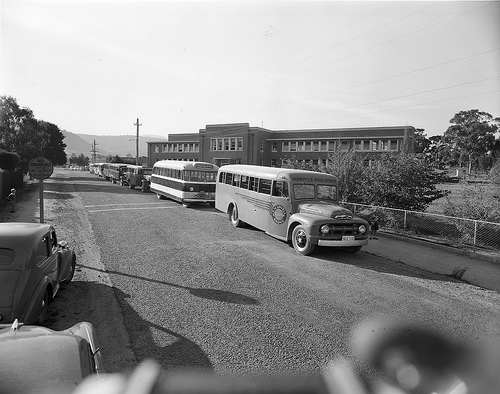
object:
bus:
[215, 162, 371, 256]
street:
[69, 168, 500, 393]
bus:
[150, 159, 218, 206]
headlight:
[321, 225, 330, 235]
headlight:
[358, 225, 367, 234]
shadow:
[43, 191, 75, 197]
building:
[146, 122, 417, 180]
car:
[0, 317, 104, 393]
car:
[0, 221, 77, 323]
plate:
[342, 235, 355, 243]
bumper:
[319, 239, 369, 247]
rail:
[151, 172, 187, 180]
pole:
[136, 117, 140, 164]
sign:
[28, 157, 55, 181]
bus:
[102, 164, 127, 186]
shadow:
[76, 262, 259, 304]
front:
[289, 172, 369, 256]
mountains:
[59, 129, 113, 158]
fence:
[337, 201, 499, 253]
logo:
[235, 192, 288, 224]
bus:
[92, 164, 103, 174]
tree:
[20, 119, 66, 180]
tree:
[0, 149, 22, 169]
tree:
[0, 93, 35, 158]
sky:
[0, 0, 498, 139]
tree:
[441, 108, 499, 176]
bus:
[86, 165, 93, 173]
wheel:
[291, 224, 318, 256]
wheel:
[343, 246, 363, 254]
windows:
[222, 138, 230, 150]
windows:
[390, 138, 398, 150]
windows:
[259, 178, 272, 196]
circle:
[270, 204, 288, 224]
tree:
[414, 128, 427, 151]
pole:
[93, 139, 97, 159]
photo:
[1, 0, 499, 393]